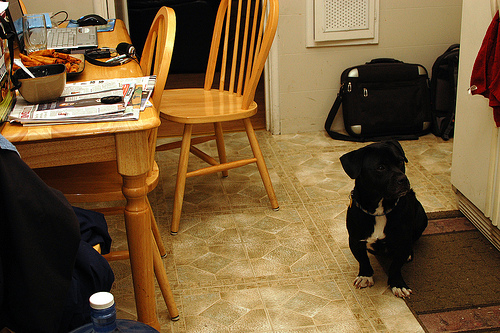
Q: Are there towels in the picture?
A: Yes, there is a towel.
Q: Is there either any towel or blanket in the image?
A: Yes, there is a towel.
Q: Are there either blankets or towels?
A: Yes, there is a towel.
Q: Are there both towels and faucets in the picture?
A: No, there is a towel but no faucets.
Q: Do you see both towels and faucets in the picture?
A: No, there is a towel but no faucets.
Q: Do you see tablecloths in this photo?
A: No, there are no tablecloths.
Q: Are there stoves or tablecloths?
A: No, there are no tablecloths or stoves.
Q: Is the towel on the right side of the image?
A: Yes, the towel is on the right of the image.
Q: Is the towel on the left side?
A: No, the towel is on the right of the image.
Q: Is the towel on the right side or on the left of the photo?
A: The towel is on the right of the image.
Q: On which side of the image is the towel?
A: The towel is on the right of the image.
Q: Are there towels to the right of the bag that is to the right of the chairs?
A: Yes, there is a towel to the right of the bag.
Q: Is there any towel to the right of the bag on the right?
A: Yes, there is a towel to the right of the bag.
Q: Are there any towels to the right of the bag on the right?
A: Yes, there is a towel to the right of the bag.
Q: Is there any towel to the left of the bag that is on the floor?
A: No, the towel is to the right of the bag.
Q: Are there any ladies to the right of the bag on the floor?
A: No, there is a towel to the right of the bag.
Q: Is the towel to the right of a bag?
A: Yes, the towel is to the right of a bag.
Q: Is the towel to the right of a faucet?
A: No, the towel is to the right of a bag.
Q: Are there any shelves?
A: No, there are no shelves.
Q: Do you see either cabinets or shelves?
A: No, there are no shelves or cabinets.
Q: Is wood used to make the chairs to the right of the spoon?
A: Yes, the chairs are made of wood.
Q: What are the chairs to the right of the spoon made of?
A: The chairs are made of wood.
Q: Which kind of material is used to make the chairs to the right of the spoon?
A: The chairs are made of wood.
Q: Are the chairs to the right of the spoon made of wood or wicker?
A: The chairs are made of wood.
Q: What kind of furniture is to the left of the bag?
A: The pieces of furniture are chairs.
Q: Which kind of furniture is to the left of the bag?
A: The pieces of furniture are chairs.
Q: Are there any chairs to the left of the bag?
A: Yes, there are chairs to the left of the bag.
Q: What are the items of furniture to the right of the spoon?
A: The pieces of furniture are chairs.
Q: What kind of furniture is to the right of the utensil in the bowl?
A: The pieces of furniture are chairs.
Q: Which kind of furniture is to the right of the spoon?
A: The pieces of furniture are chairs.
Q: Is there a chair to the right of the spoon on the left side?
A: Yes, there are chairs to the right of the spoon.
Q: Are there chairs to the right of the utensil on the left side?
A: Yes, there are chairs to the right of the spoon.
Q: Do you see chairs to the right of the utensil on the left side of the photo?
A: Yes, there are chairs to the right of the spoon.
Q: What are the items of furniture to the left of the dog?
A: The pieces of furniture are chairs.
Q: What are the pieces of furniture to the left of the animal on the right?
A: The pieces of furniture are chairs.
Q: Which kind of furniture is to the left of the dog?
A: The pieces of furniture are chairs.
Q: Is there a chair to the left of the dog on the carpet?
A: Yes, there are chairs to the left of the dog.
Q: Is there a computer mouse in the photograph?
A: Yes, there is a computer mouse.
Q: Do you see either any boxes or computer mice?
A: Yes, there is a computer mouse.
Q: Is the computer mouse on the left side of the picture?
A: Yes, the computer mouse is on the left of the image.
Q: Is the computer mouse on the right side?
A: No, the computer mouse is on the left of the image.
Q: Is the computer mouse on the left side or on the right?
A: The computer mouse is on the left of the image.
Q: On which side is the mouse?
A: The mouse is on the left of the image.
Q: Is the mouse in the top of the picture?
A: Yes, the mouse is in the top of the image.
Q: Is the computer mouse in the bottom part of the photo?
A: No, the computer mouse is in the top of the image.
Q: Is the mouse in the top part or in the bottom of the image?
A: The mouse is in the top of the image.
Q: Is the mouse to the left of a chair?
A: Yes, the mouse is to the left of a chair.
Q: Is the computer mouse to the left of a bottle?
A: No, the computer mouse is to the left of a chair.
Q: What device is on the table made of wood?
A: The device is a computer mouse.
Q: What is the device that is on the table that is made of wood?
A: The device is a computer mouse.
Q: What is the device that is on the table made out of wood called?
A: The device is a computer mouse.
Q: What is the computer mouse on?
A: The computer mouse is on the table.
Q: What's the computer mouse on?
A: The computer mouse is on the table.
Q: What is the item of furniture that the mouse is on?
A: The piece of furniture is a table.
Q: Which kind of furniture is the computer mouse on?
A: The mouse is on the table.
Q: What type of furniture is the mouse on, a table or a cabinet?
A: The mouse is on a table.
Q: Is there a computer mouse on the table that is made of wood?
A: Yes, there is a computer mouse on the table.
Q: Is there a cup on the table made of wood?
A: No, there is a computer mouse on the table.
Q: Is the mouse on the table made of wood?
A: Yes, the mouse is on the table.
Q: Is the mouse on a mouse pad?
A: No, the mouse is on the table.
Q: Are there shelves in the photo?
A: No, there are no shelves.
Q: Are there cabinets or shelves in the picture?
A: No, there are no shelves or cabinets.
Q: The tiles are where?
A: The tiles are on the floor.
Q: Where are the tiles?
A: The tiles are on the floor.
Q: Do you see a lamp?
A: No, there are no lamps.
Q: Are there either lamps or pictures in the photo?
A: No, there are no lamps or pictures.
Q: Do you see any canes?
A: No, there are no canes.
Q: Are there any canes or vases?
A: No, there are no canes or vases.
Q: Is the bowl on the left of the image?
A: Yes, the bowl is on the left of the image.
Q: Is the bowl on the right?
A: No, the bowl is on the left of the image.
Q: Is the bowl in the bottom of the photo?
A: No, the bowl is in the top of the image.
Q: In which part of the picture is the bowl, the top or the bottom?
A: The bowl is in the top of the image.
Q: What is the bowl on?
A: The bowl is on the table.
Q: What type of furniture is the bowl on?
A: The bowl is on the table.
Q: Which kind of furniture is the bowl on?
A: The bowl is on the table.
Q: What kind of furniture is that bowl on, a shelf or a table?
A: The bowl is on a table.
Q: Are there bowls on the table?
A: Yes, there is a bowl on the table.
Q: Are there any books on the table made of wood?
A: No, there is a bowl on the table.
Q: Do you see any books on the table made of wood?
A: No, there is a bowl on the table.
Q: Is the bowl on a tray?
A: No, the bowl is on a table.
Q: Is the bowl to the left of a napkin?
A: No, the bowl is to the left of the chair.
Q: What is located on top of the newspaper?
A: The bowl is on top of the newspaper.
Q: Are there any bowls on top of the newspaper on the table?
A: Yes, there is a bowl on top of the newspaper.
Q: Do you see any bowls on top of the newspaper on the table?
A: Yes, there is a bowl on top of the newspaper.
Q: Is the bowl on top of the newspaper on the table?
A: Yes, the bowl is on top of the newspaper.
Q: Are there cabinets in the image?
A: No, there are no cabinets.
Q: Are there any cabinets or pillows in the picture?
A: No, there are no cabinets or pillows.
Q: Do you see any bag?
A: Yes, there is a bag.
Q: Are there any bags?
A: Yes, there is a bag.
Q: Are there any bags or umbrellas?
A: Yes, there is a bag.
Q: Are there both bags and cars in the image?
A: No, there is a bag but no cars.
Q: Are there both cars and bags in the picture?
A: No, there is a bag but no cars.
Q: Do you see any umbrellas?
A: No, there are no umbrellas.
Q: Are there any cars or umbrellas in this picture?
A: No, there are no umbrellas or cars.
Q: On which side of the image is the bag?
A: The bag is on the right of the image.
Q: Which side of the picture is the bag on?
A: The bag is on the right of the image.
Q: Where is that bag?
A: The bag is on the floor.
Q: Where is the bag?
A: The bag is on the floor.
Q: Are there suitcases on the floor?
A: No, there is a bag on the floor.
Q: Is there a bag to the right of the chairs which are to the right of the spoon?
A: Yes, there is a bag to the right of the chairs.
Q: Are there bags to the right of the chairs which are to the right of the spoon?
A: Yes, there is a bag to the right of the chairs.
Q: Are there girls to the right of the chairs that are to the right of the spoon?
A: No, there is a bag to the right of the chairs.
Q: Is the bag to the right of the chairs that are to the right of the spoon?
A: Yes, the bag is to the right of the chairs.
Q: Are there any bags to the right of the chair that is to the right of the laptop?
A: Yes, there is a bag to the right of the chair.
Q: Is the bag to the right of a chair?
A: Yes, the bag is to the right of a chair.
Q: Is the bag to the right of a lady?
A: No, the bag is to the right of a chair.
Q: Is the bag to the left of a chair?
A: No, the bag is to the right of a chair.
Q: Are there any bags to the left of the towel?
A: Yes, there is a bag to the left of the towel.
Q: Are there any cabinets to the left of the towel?
A: No, there is a bag to the left of the towel.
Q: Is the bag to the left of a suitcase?
A: No, the bag is to the left of the towel.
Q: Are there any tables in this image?
A: Yes, there is a table.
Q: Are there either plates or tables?
A: Yes, there is a table.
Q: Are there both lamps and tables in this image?
A: No, there is a table but no lamps.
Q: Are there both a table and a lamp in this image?
A: No, there is a table but no lamps.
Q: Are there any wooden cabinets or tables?
A: Yes, there is a wood table.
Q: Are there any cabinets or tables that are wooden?
A: Yes, the table is wooden.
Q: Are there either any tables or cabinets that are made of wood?
A: Yes, the table is made of wood.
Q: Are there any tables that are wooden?
A: Yes, there is a wood table.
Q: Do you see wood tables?
A: Yes, there is a wood table.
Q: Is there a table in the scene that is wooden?
A: Yes, there is a table that is wooden.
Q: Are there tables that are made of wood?
A: Yes, there is a table that is made of wood.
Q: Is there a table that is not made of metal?
A: Yes, there is a table that is made of wood.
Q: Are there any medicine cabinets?
A: No, there are no medicine cabinets.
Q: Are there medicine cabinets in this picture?
A: No, there are no medicine cabinets.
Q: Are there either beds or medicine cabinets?
A: No, there are no medicine cabinets or beds.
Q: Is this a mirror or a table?
A: This is a table.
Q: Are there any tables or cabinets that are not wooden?
A: No, there is a table but it is wooden.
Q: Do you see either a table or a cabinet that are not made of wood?
A: No, there is a table but it is made of wood.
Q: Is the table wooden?
A: Yes, the table is wooden.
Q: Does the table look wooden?
A: Yes, the table is wooden.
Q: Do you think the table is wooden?
A: Yes, the table is wooden.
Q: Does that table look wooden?
A: Yes, the table is wooden.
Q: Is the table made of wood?
A: Yes, the table is made of wood.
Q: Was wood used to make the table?
A: Yes, the table is made of wood.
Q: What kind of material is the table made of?
A: The table is made of wood.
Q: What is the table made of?
A: The table is made of wood.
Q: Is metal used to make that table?
A: No, the table is made of wood.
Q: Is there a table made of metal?
A: No, there is a table but it is made of wood.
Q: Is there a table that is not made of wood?
A: No, there is a table but it is made of wood.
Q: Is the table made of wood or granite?
A: The table is made of wood.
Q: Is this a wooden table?
A: Yes, this is a wooden table.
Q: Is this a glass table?
A: No, this is a wooden table.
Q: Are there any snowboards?
A: No, there are no snowboards.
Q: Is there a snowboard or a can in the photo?
A: No, there are no snowboards or cans.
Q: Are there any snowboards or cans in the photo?
A: No, there are no snowboards or cans.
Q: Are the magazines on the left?
A: Yes, the magazines are on the left of the image.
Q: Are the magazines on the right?
A: No, the magazines are on the left of the image.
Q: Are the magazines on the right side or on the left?
A: The magazines are on the left of the image.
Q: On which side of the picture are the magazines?
A: The magazines are on the left of the image.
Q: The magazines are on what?
A: The magazines are on the table.